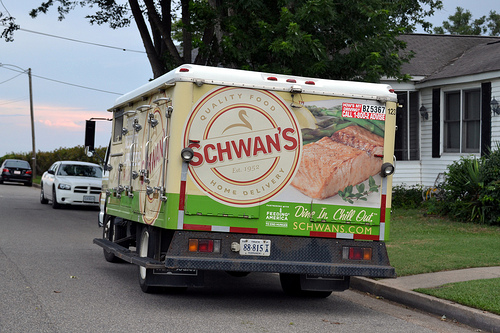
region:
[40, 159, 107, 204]
A parked car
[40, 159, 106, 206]
the car is small and white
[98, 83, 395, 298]
A medium-sized truck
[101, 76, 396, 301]
The truck is yellow with green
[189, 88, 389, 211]
A sign on the truck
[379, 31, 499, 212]
A white wooden house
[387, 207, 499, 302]
neatly cut green grass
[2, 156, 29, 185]
A parked car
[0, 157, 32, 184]
The car is small and black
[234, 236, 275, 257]
A license plate on the back of the truck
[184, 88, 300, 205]
big round logo on back of food delivery truck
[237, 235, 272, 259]
license plate on back of delivery truck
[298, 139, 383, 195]
picture of food on back of truck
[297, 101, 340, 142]
picture of asparagus on back of truck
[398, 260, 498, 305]
sidewalk on right side of food delivery truck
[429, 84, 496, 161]
window with black shutters on house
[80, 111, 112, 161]
rear-view mirror of food delivery truck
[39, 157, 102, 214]
white car in front of food delivery truck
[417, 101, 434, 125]
black lamp on outside of white house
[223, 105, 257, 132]
swan logo for food delivery truck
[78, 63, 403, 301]
the truck is for food delivery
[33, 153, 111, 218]
the car is white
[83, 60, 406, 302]
the truck is parked in the road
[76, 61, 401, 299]
the truck is in front of a house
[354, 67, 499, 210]
the house is white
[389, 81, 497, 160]
the house has black shutters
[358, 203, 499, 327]
the grass is green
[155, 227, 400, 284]
the truck has a black bumper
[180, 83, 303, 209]
the truck has a logo on the back of it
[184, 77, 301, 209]
the logo is round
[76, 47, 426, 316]
the truck is parked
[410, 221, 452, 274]
the grass is green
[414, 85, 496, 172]
the walls are white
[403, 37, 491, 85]
the roof is brown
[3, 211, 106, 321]
the street is gray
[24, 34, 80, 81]
the sky is blue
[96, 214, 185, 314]
the tires are black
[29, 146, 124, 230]
the car is parked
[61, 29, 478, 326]
the truck is in front of the house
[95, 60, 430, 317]
Schwan's refrigerated truck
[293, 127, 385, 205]
salmon fillet on the back of a schwan's truck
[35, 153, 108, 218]
white sedan parked on the street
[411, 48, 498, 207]
white house with black shutters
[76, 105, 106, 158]
broken streetlight hanging over the street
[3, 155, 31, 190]
black sedan parked on the street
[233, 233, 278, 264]
license plate on the back of a truck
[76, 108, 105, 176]
side view mirror on a truck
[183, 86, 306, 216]
circular schwan's logo on the back of a truck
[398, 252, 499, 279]
sidewalk on a residential block